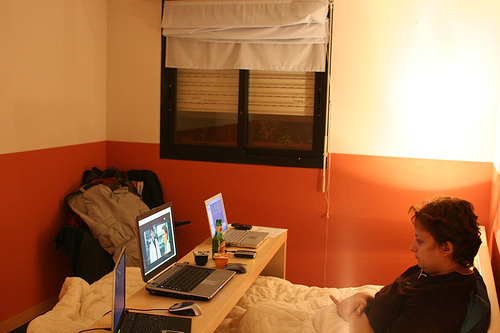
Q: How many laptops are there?
A: Three.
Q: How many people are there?
A: One.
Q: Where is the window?
A: To the left.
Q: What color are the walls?
A: White and orange.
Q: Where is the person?
A: In the bed.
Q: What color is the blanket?
A: White.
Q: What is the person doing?
A: Looking at a computer screen.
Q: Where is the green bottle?
A: Beside the laptop.